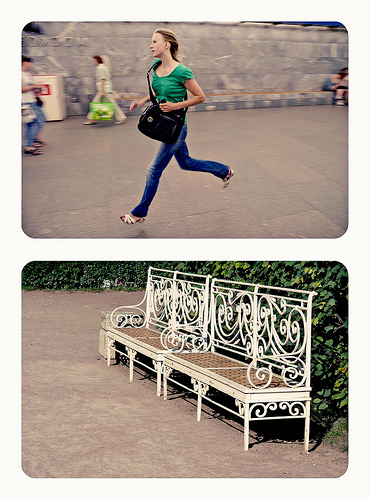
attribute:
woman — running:
[118, 28, 235, 224]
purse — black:
[137, 57, 189, 144]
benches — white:
[106, 266, 317, 449]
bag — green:
[89, 102, 117, 121]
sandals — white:
[120, 167, 236, 225]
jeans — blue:
[131, 120, 230, 216]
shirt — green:
[150, 63, 196, 115]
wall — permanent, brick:
[22, 22, 348, 121]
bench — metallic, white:
[161, 278, 318, 448]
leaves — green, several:
[317, 318, 340, 396]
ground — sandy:
[36, 419, 188, 472]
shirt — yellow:
[95, 65, 112, 100]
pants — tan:
[85, 93, 126, 118]